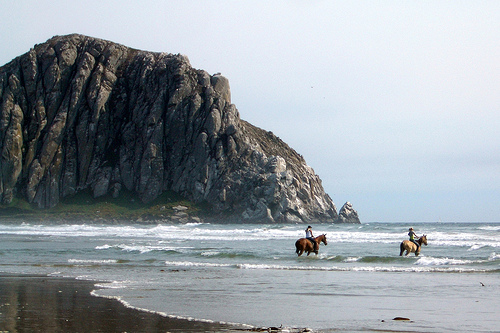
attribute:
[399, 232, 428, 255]
horse — brown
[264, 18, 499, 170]
sky — blue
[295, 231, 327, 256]
horse — brown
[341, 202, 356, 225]
rocks — large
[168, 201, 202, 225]
rocks — large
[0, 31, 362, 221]
rocks — large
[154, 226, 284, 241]
waves — white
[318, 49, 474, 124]
sky — blue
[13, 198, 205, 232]
grass — green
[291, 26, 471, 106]
sky — blue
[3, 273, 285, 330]
sand — wet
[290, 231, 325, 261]
horse — brown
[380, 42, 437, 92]
sky — cloudy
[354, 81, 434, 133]
cloud — white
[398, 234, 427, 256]
horse — light brown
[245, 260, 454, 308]
water — wavy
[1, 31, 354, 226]
hill — rocky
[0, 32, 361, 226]
rocky cliffs — rocky 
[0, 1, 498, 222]
sky — gray, overhead, hazy, cloudy, blue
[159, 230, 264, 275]
waves — wavy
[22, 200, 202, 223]
hill — grassy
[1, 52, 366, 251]
rock — large, mountainous